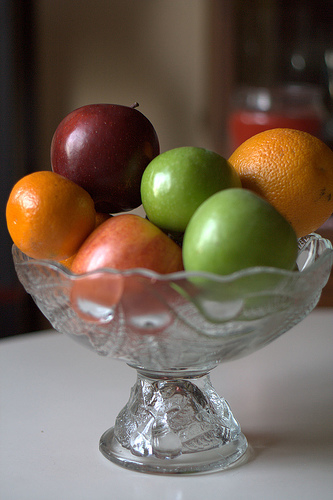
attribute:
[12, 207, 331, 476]
dish — glass, clear, ornamental, etching, crystal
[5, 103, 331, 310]
fruit — colorful, mixed, assorted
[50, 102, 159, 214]
apple — red, dark red, ripe, delicious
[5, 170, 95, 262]
tangerine — orange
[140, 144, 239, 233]
apple — green, stemless, granny smith, dish, shiny, lovely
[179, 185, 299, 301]
apple — green, stemless, granny smith, dish, shiny, lovely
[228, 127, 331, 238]
orange — ripe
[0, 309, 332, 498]
table — white, bright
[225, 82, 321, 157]
candle — red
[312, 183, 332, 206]
spot — black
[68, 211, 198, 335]
apple — pink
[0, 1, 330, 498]
restaurant — photo